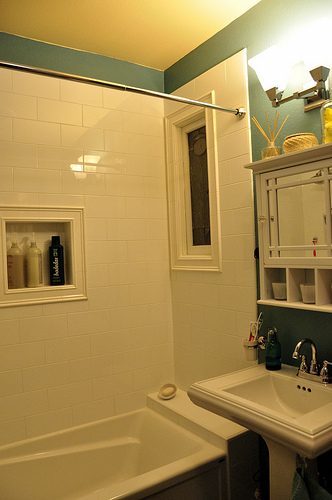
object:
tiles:
[110, 196, 135, 217]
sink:
[187, 357, 332, 459]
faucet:
[292, 338, 319, 376]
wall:
[255, 27, 278, 39]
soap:
[162, 386, 173, 395]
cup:
[245, 348, 257, 360]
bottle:
[261, 141, 279, 159]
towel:
[290, 477, 328, 495]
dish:
[159, 383, 177, 400]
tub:
[0, 387, 270, 500]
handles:
[297, 354, 332, 383]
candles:
[252, 105, 291, 141]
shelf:
[258, 258, 332, 311]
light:
[247, 43, 286, 91]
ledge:
[3, 220, 73, 290]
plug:
[127, 458, 139, 467]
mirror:
[186, 124, 211, 245]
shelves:
[243, 140, 332, 273]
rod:
[128, 85, 246, 117]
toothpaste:
[248, 320, 257, 341]